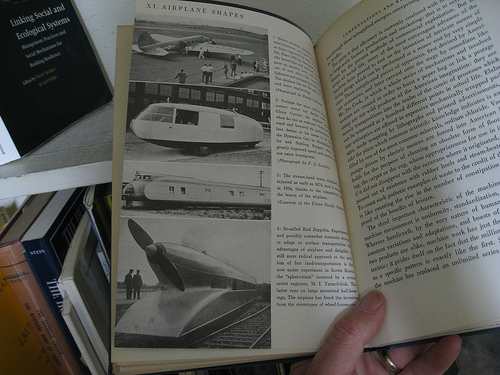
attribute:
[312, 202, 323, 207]
word — black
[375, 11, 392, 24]
word — black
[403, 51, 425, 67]
word — black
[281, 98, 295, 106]
word — black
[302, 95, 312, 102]
word — black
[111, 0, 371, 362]
page — white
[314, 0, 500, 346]
page — white, unillustrated, printed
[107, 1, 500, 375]
book — writings, being read by a pers, open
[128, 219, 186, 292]
propeller — black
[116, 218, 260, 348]
plane — a type of airplane, metal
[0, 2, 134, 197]
surface — white, a white surface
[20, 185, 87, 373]
book — black, writings, black colored, standing vertically, hard covered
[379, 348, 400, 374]
ring — gold, what this is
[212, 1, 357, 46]
table — a white surface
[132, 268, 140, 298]
men — standing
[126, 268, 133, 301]
men — standing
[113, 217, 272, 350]
photograph — black, white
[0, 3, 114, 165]
black book — writings, black colored, standing, hard covered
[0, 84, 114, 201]
shelf — white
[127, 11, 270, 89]
photograph — black, white, on top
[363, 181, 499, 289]
paragraph — the last one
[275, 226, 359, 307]
paragraph — the last one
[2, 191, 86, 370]
book — hard covered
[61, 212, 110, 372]
book — soft covered, writings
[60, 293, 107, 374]
book — soft covered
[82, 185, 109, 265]
book — soft covered, writings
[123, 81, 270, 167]
photograph — black, white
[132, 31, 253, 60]
airplane — metal, white colored, a jet, a type of airplane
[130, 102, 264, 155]
vehicle — curved, broad, metal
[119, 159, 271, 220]
photograph — black, white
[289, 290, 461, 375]
person — married